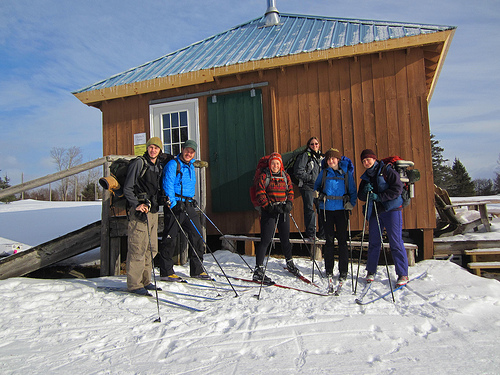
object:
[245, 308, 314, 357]
floor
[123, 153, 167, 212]
jacket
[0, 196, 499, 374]
snow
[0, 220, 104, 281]
ramp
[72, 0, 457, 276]
building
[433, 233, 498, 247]
steps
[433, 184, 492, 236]
chair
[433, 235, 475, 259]
deck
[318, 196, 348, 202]
strap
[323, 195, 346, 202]
waist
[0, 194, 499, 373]
ground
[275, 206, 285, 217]
hand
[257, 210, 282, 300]
pole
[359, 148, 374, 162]
cap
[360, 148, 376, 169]
head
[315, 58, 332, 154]
shed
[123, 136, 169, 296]
man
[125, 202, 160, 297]
pants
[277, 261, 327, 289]
skis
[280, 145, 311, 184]
backpacks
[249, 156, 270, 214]
backpack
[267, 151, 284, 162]
hat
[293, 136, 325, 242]
one person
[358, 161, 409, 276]
blue clothes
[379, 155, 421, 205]
backpack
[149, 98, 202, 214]
door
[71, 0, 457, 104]
roof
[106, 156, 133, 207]
backpack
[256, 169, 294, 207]
jacket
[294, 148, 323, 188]
jacket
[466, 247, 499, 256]
steps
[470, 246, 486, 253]
snow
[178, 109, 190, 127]
window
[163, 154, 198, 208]
jacket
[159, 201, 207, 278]
pants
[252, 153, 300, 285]
boy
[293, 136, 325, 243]
woman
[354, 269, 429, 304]
skis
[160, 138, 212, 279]
man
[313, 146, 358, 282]
sport kit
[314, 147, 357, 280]
person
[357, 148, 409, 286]
man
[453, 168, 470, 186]
leaves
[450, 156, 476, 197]
tree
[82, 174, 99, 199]
tree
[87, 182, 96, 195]
leaves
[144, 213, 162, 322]
ski pole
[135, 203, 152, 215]
hand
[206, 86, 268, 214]
door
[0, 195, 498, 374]
field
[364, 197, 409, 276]
pants